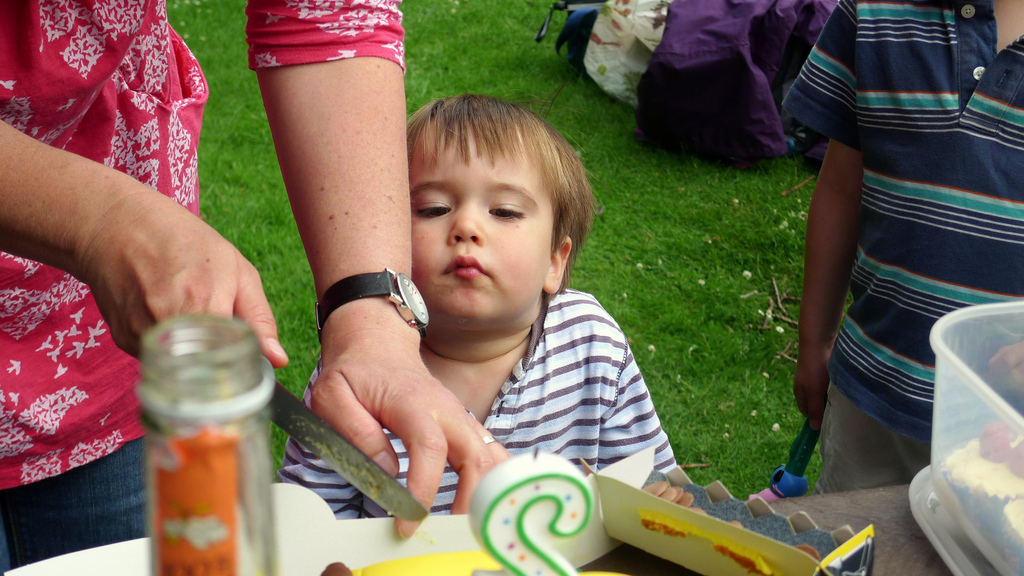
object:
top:
[131, 316, 278, 419]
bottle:
[132, 313, 275, 576]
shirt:
[0, 0, 405, 489]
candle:
[473, 450, 604, 576]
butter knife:
[269, 381, 430, 520]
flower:
[742, 270, 751, 281]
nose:
[447, 203, 485, 246]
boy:
[280, 93, 699, 526]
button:
[496, 402, 502, 409]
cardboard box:
[600, 444, 880, 576]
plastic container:
[907, 302, 1024, 576]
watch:
[315, 268, 430, 341]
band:
[317, 272, 396, 327]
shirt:
[778, 0, 1024, 441]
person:
[0, 0, 515, 572]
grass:
[165, 0, 831, 503]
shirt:
[276, 288, 684, 525]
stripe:
[506, 356, 629, 396]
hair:
[405, 94, 594, 294]